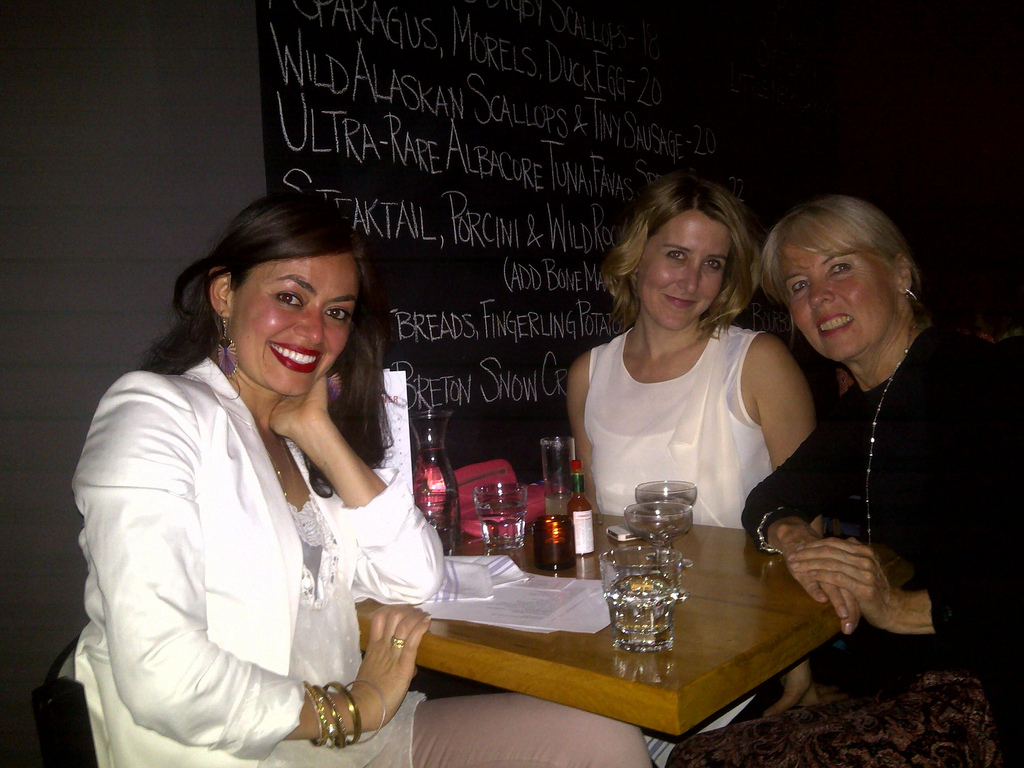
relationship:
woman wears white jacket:
[76, 194, 646, 768] [76, 356, 449, 768]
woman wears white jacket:
[76, 194, 646, 768] [66, 348, 458, 767]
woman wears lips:
[76, 194, 646, 768] [268, 339, 323, 374]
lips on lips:
[268, 339, 323, 374] [262, 335, 326, 371]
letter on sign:
[480, 357, 502, 403] [256, 0, 785, 476]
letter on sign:
[414, 197, 437, 246] [255, 20, 679, 483]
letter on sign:
[264, 20, 307, 90] [255, 20, 679, 483]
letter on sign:
[271, 95, 311, 165] [255, 20, 679, 483]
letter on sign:
[473, 357, 508, 406] [255, 20, 679, 483]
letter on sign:
[387, 308, 422, 348] [255, 20, 679, 483]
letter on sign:
[276, 91, 308, 152] [256, 0, 785, 476]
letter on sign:
[395, 311, 415, 341] [256, 0, 785, 476]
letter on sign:
[417, 202, 438, 242] [256, 0, 785, 476]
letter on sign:
[476, 295, 495, 346] [256, 0, 785, 476]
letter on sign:
[441, 310, 467, 337] [256, 0, 785, 476]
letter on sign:
[422, 312, 439, 342] [261, 7, 720, 479]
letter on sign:
[409, 299, 432, 337] [261, 7, 720, 479]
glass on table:
[579, 539, 685, 651] [352, 513, 841, 732]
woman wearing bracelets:
[76, 194, 646, 768] [289, 662, 391, 752]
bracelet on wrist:
[280, 665, 350, 729] [292, 636, 432, 732]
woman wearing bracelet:
[180, 249, 484, 670] [280, 665, 350, 729]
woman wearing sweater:
[707, 185, 1021, 762] [737, 320, 1021, 742]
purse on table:
[434, 448, 558, 559] [356, 499, 918, 737]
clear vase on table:
[329, 355, 620, 619] [356, 499, 918, 737]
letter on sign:
[456, 308, 482, 338] [261, 7, 720, 479]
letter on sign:
[276, 91, 308, 152] [261, 7, 720, 479]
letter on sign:
[304, 96, 333, 157] [261, 7, 720, 479]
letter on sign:
[269, 22, 304, 85] [261, 7, 720, 479]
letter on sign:
[339, 35, 376, 102] [261, 7, 720, 479]